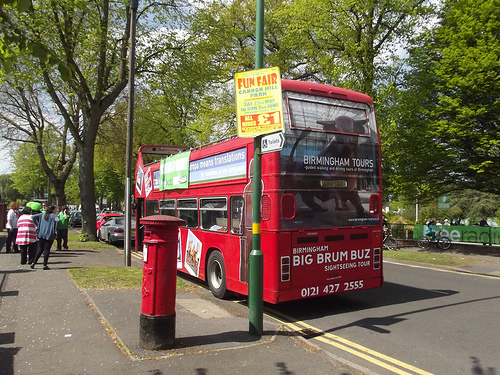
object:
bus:
[134, 79, 385, 304]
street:
[73, 215, 499, 375]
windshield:
[282, 190, 381, 227]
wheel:
[201, 250, 230, 304]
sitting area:
[135, 129, 265, 168]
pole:
[247, 0, 269, 338]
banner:
[156, 151, 192, 193]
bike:
[413, 230, 452, 252]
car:
[94, 210, 120, 234]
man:
[30, 202, 59, 270]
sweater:
[31, 211, 60, 240]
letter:
[291, 255, 302, 267]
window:
[198, 197, 230, 233]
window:
[230, 194, 245, 235]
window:
[175, 197, 200, 230]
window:
[159, 197, 177, 220]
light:
[279, 255, 291, 284]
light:
[372, 246, 383, 271]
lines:
[235, 298, 431, 375]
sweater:
[15, 214, 37, 245]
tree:
[406, 1, 500, 204]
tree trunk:
[78, 145, 103, 241]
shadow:
[238, 280, 459, 327]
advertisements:
[276, 88, 382, 230]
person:
[15, 208, 38, 265]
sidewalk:
[1, 224, 354, 372]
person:
[425, 220, 437, 244]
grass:
[67, 267, 196, 291]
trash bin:
[137, 213, 191, 351]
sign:
[231, 67, 286, 138]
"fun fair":
[235, 73, 278, 89]